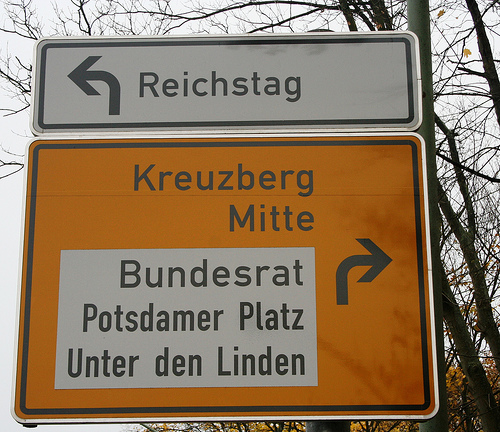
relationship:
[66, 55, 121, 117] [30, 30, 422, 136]
arrow on sign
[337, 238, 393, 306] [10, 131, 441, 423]
arrow on sign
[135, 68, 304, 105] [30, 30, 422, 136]
writing on sign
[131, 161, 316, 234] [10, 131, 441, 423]
writing on sign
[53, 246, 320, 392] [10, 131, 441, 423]
box on sign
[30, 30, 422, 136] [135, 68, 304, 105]
sign saying reichstag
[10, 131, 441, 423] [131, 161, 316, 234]
sign saying kreuzberg mitte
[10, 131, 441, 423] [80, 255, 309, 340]
sign saying bundesrat potsdamer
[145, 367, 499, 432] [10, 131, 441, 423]
trees are behind sign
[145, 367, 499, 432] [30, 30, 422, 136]
trees are behind sign